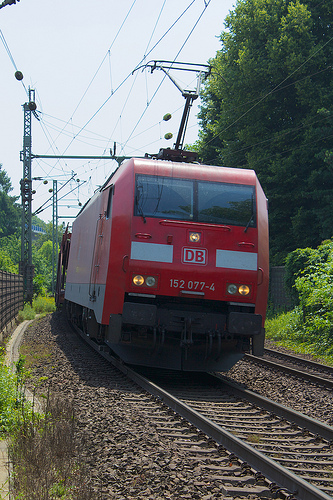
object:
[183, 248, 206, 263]
logo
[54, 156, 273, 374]
train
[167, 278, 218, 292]
152 077-4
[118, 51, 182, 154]
catenary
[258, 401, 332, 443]
bed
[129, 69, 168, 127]
pantograph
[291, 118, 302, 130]
leaves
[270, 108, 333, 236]
trees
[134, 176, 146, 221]
wiper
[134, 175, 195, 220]
windshield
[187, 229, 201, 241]
headlamp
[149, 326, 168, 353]
bumper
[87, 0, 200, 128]
wires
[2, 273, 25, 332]
fence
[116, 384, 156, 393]
plank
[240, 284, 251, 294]
lights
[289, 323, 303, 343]
grass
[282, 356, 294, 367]
gravel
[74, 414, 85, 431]
dirt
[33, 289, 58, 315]
bushes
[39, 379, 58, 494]
weed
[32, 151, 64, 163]
pole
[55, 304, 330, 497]
rails